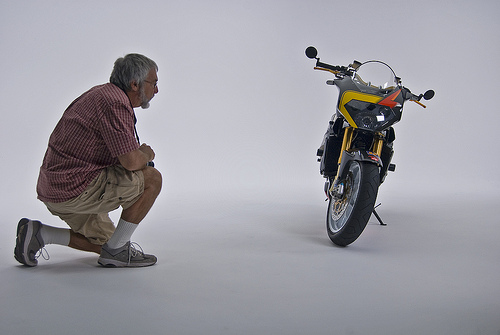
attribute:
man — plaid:
[4, 49, 175, 274]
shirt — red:
[32, 79, 141, 201]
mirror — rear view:
[415, 88, 435, 102]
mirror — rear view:
[303, 46, 322, 63]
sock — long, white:
[105, 217, 138, 249]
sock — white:
[38, 219, 71, 246]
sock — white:
[95, 221, 134, 253]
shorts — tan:
[42, 165, 142, 245]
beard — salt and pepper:
[138, 79, 148, 107]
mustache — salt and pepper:
[148, 92, 155, 99]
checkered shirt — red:
[33, 77, 139, 201]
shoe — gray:
[104, 245, 156, 264]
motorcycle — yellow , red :
[286, 35, 446, 250]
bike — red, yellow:
[302, 44, 435, 249]